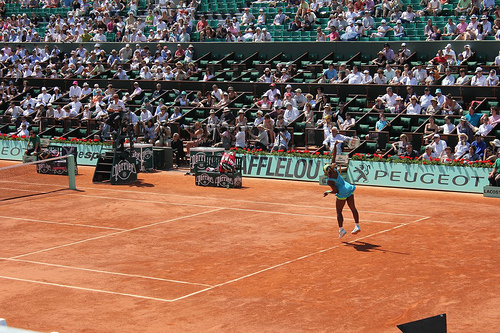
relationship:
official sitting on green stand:
[105, 94, 125, 134] [93, 112, 138, 184]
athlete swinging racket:
[323, 140, 361, 238] [336, 128, 366, 151]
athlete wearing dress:
[323, 140, 361, 238] [326, 168, 355, 200]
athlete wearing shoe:
[323, 140, 361, 238] [336, 227, 347, 239]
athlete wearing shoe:
[323, 140, 361, 238] [350, 224, 361, 234]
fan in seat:
[320, 125, 353, 155] [400, 117, 411, 122]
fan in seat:
[423, 145, 439, 163] [240, 75, 249, 81]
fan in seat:
[426, 133, 446, 156] [293, 128, 303, 135]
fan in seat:
[440, 147, 455, 160] [358, 123, 368, 128]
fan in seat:
[453, 132, 471, 160] [198, 60, 207, 65]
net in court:
[5, 155, 85, 199] [17, 156, 297, 313]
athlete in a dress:
[316, 147, 369, 239] [318, 163, 356, 203]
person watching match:
[253, 123, 306, 152] [6, 153, 361, 303]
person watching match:
[199, 83, 225, 108] [1, 138, 498, 323]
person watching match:
[127, 81, 144, 100] [6, 153, 361, 303]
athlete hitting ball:
[323, 140, 361, 238] [235, 109, 389, 173]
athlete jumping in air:
[323, 140, 361, 238] [231, 101, 400, 217]